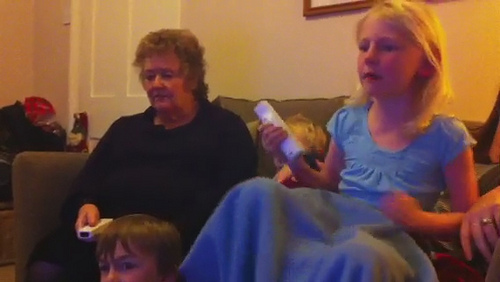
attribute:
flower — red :
[14, 80, 64, 134]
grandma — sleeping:
[112, 17, 213, 124]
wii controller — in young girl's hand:
[244, 89, 313, 169]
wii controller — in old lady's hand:
[64, 200, 118, 244]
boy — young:
[92, 205, 190, 278]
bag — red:
[25, 92, 60, 147]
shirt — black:
[60, 95, 256, 272]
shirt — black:
[98, 107, 252, 231]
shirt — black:
[58, 74, 296, 254]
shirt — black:
[95, 122, 246, 217]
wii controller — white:
[245, 96, 321, 175]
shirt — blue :
[321, 98, 476, 240]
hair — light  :
[349, 2, 459, 133]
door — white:
[61, 0, 177, 145]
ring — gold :
[479, 210, 492, 228]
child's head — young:
[91, 212, 175, 279]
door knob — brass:
[71, 112, 87, 123]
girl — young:
[311, 2, 461, 273]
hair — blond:
[399, 4, 440, 45]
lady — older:
[114, 25, 241, 183]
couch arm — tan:
[10, 151, 67, 228]